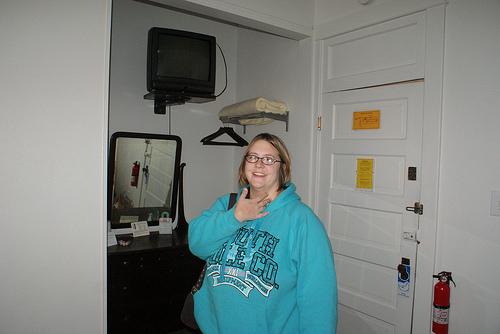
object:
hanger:
[397, 264, 408, 280]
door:
[310, 0, 446, 334]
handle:
[397, 264, 408, 280]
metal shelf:
[219, 110, 290, 135]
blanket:
[218, 96, 287, 126]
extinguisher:
[428, 272, 457, 334]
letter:
[249, 251, 266, 277]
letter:
[226, 243, 247, 269]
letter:
[208, 239, 229, 265]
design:
[206, 227, 279, 298]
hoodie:
[187, 182, 338, 334]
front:
[188, 182, 337, 334]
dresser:
[110, 131, 210, 333]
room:
[0, 0, 498, 331]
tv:
[147, 27, 220, 97]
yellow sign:
[352, 110, 382, 129]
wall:
[111, 0, 308, 235]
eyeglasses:
[243, 155, 281, 166]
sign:
[355, 158, 374, 189]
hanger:
[200, 116, 250, 147]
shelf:
[143, 90, 217, 114]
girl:
[190, 131, 338, 333]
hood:
[236, 182, 303, 214]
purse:
[179, 263, 212, 328]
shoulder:
[208, 193, 244, 213]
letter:
[229, 227, 254, 246]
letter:
[261, 258, 279, 290]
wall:
[239, 0, 499, 334]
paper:
[352, 110, 380, 130]